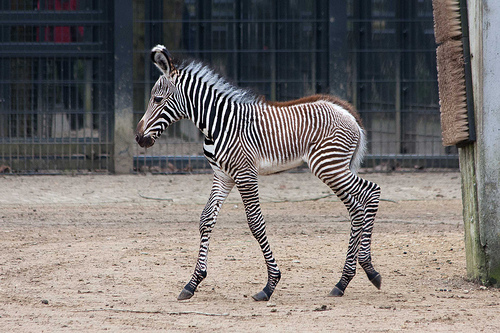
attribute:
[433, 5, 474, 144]
brush — rectangular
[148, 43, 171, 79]
ears — white, black, striped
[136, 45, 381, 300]
zebra — white, black, striped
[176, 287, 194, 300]
hoof — black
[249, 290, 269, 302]
hoof — black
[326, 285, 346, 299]
hoof — black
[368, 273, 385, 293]
hoof — black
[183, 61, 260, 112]
mane — striped, black, white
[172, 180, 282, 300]
frontlegs — black, white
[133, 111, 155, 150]
nose — black, white, striped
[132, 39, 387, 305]
zebra hoof — black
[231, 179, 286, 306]
leg — long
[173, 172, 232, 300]
leg — long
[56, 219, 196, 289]
ground — dirt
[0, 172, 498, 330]
dirt — brown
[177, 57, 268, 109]
mane — black, white, striped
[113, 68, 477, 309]
zebra — striped, black, hite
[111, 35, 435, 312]
zebra — white, black, striped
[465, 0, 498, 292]
wall — gray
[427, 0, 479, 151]
brush — rectagular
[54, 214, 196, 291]
ground — dirt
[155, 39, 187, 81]
ears — black, white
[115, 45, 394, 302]
zebra — striped, black, white